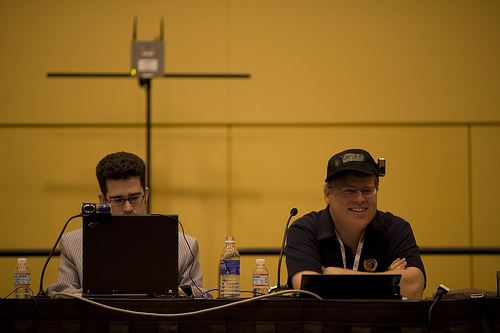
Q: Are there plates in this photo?
A: No, there are no plates.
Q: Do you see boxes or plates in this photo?
A: No, there are no plates or boxes.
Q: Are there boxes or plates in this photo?
A: No, there are no plates or boxes.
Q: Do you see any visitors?
A: No, there are no visitors.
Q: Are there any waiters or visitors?
A: No, there are no visitors or waiters.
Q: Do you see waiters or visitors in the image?
A: No, there are no visitors or waiters.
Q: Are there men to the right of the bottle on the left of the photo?
A: Yes, there is a man to the right of the bottle.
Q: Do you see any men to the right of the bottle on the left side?
A: Yes, there is a man to the right of the bottle.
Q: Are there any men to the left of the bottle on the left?
A: No, the man is to the right of the bottle.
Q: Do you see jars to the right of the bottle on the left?
A: No, there is a man to the right of the bottle.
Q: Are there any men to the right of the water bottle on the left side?
A: Yes, there is a man to the right of the water bottle.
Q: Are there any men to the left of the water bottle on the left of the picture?
A: No, the man is to the right of the water bottle.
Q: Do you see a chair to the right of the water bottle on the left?
A: No, there is a man to the right of the water bottle.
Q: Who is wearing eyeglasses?
A: The man is wearing eyeglasses.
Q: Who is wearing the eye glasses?
A: The man is wearing eyeglasses.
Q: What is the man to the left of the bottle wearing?
A: The man is wearing eyeglasses.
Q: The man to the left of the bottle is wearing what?
A: The man is wearing eyeglasses.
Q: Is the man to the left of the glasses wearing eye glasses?
A: Yes, the man is wearing eye glasses.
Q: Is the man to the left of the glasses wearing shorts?
A: No, the man is wearing eye glasses.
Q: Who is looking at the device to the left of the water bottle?
A: The man is looking at the computer.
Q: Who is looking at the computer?
A: The man is looking at the computer.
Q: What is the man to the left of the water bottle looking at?
A: The man is looking at the computer.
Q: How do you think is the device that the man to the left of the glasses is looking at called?
A: The device is a computer.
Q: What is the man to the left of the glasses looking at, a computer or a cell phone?
A: The man is looking at a computer.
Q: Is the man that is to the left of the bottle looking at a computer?
A: Yes, the man is looking at a computer.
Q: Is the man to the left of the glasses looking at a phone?
A: No, the man is looking at a computer.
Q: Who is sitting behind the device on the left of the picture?
A: The man is sitting behind the computer.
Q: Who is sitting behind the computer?
A: The man is sitting behind the computer.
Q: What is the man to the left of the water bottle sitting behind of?
A: The man is sitting behind the computer.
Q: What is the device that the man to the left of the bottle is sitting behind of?
A: The device is a computer.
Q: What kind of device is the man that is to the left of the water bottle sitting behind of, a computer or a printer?
A: The man is sitting behind a computer.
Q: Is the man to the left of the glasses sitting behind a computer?
A: Yes, the man is sitting behind a computer.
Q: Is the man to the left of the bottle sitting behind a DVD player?
A: No, the man is sitting behind a computer.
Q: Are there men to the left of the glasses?
A: Yes, there is a man to the left of the glasses.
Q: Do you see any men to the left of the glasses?
A: Yes, there is a man to the left of the glasses.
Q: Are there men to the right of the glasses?
A: No, the man is to the left of the glasses.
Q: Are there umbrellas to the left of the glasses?
A: No, there is a man to the left of the glasses.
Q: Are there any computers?
A: Yes, there is a computer.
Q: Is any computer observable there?
A: Yes, there is a computer.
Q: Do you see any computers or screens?
A: Yes, there is a computer.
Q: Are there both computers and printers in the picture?
A: No, there is a computer but no printers.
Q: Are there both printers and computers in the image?
A: No, there is a computer but no printers.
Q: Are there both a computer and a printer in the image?
A: No, there is a computer but no printers.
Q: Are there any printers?
A: No, there are no printers.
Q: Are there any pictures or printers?
A: No, there are no printers or pictures.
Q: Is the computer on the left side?
A: Yes, the computer is on the left of the image.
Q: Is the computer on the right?
A: No, the computer is on the left of the image.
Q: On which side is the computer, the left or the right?
A: The computer is on the left of the image.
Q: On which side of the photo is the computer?
A: The computer is on the left of the image.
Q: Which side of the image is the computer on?
A: The computer is on the left of the image.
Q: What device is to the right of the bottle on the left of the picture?
A: The device is a computer.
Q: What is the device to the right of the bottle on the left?
A: The device is a computer.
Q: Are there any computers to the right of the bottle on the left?
A: Yes, there is a computer to the right of the bottle.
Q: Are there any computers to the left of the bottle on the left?
A: No, the computer is to the right of the bottle.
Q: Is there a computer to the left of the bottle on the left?
A: No, the computer is to the right of the bottle.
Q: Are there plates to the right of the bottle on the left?
A: No, there is a computer to the right of the bottle.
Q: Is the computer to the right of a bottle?
A: Yes, the computer is to the right of a bottle.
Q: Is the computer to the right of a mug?
A: No, the computer is to the right of a bottle.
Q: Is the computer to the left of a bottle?
A: No, the computer is to the right of a bottle.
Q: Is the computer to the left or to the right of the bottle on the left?
A: The computer is to the right of the bottle.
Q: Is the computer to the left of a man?
A: Yes, the computer is to the left of a man.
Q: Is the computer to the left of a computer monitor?
A: No, the computer is to the left of a man.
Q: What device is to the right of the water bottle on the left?
A: The device is a computer.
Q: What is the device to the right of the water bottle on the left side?
A: The device is a computer.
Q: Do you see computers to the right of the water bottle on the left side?
A: Yes, there is a computer to the right of the water bottle.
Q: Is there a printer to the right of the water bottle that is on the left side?
A: No, there is a computer to the right of the water bottle.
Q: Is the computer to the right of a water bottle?
A: Yes, the computer is to the right of a water bottle.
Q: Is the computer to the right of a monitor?
A: No, the computer is to the right of a water bottle.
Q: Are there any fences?
A: No, there are no fences.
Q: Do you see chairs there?
A: No, there are no chairs.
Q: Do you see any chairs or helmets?
A: No, there are no chairs or helmets.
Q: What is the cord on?
A: The cord is on the table.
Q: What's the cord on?
A: The cord is on the table.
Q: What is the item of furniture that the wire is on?
A: The piece of furniture is a table.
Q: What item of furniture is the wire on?
A: The wire is on the table.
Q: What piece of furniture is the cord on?
A: The wire is on the table.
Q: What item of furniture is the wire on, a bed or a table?
A: The wire is on a table.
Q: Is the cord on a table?
A: Yes, the cord is on a table.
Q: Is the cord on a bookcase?
A: No, the cord is on a table.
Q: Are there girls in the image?
A: No, there are no girls.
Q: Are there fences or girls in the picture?
A: No, there are no girls or fences.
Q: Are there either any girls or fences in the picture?
A: No, there are no girls or fences.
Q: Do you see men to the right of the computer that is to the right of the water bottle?
A: Yes, there is a man to the right of the computer.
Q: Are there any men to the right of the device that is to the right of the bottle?
A: Yes, there is a man to the right of the computer.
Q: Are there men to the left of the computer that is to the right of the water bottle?
A: No, the man is to the right of the computer.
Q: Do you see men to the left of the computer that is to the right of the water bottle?
A: No, the man is to the right of the computer.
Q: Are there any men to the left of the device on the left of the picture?
A: No, the man is to the right of the computer.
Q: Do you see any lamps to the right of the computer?
A: No, there is a man to the right of the computer.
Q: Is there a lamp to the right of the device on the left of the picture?
A: No, there is a man to the right of the computer.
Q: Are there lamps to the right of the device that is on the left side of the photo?
A: No, there is a man to the right of the computer.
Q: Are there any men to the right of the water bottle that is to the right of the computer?
A: Yes, there is a man to the right of the water bottle.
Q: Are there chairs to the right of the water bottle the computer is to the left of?
A: No, there is a man to the right of the water bottle.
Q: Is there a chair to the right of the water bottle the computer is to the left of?
A: No, there is a man to the right of the water bottle.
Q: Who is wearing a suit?
A: The man is wearing a suit.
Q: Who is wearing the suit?
A: The man is wearing a suit.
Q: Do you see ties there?
A: No, there are no ties.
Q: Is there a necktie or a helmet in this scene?
A: No, there are no ties or helmets.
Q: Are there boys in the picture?
A: No, there are no boys.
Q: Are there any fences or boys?
A: No, there are no boys or fences.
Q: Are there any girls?
A: No, there are no girls.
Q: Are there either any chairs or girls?
A: No, there are no girls or chairs.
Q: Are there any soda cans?
A: No, there are no soda cans.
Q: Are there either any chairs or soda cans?
A: No, there are no soda cans or chairs.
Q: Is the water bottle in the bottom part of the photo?
A: Yes, the water bottle is in the bottom of the image.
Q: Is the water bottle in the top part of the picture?
A: No, the water bottle is in the bottom of the image.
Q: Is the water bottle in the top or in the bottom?
A: The water bottle is in the bottom of the image.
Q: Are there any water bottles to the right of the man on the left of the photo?
A: Yes, there is a water bottle to the right of the man.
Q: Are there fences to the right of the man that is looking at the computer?
A: No, there is a water bottle to the right of the man.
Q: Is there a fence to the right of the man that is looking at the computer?
A: No, there is a water bottle to the right of the man.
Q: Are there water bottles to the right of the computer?
A: Yes, there is a water bottle to the right of the computer.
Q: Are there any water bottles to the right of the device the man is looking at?
A: Yes, there is a water bottle to the right of the computer.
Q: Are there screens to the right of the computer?
A: No, there is a water bottle to the right of the computer.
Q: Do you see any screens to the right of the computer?
A: No, there is a water bottle to the right of the computer.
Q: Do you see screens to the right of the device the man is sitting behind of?
A: No, there is a water bottle to the right of the computer.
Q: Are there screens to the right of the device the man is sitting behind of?
A: No, there is a water bottle to the right of the computer.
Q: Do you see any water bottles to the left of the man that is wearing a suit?
A: Yes, there is a water bottle to the left of the man.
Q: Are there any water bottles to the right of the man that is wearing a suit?
A: No, the water bottle is to the left of the man.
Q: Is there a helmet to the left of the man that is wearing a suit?
A: No, there is a water bottle to the left of the man.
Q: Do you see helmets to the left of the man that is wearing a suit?
A: No, there is a water bottle to the left of the man.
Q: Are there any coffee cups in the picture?
A: No, there are no coffee cups.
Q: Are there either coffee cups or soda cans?
A: No, there are no coffee cups or soda cans.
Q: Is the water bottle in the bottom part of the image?
A: Yes, the water bottle is in the bottom of the image.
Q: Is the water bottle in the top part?
A: No, the water bottle is in the bottom of the image.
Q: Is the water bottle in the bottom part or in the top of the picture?
A: The water bottle is in the bottom of the image.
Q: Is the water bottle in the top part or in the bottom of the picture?
A: The water bottle is in the bottom of the image.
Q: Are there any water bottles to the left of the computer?
A: Yes, there is a water bottle to the left of the computer.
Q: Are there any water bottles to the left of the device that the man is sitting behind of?
A: Yes, there is a water bottle to the left of the computer.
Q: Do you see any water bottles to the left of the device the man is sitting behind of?
A: Yes, there is a water bottle to the left of the computer.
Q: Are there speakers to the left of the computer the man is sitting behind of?
A: No, there is a water bottle to the left of the computer.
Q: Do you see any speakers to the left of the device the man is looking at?
A: No, there is a water bottle to the left of the computer.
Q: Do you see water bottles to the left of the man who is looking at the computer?
A: Yes, there is a water bottle to the left of the man.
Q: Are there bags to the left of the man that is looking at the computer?
A: No, there is a water bottle to the left of the man.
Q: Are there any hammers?
A: No, there are no hammers.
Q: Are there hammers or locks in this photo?
A: No, there are no hammers or locks.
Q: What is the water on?
A: The water is on the table.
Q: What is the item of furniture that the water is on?
A: The piece of furniture is a table.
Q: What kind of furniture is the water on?
A: The water is on the table.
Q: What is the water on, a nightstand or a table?
A: The water is on a table.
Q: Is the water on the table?
A: Yes, the water is on the table.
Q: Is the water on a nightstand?
A: No, the water is on the table.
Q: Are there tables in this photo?
A: Yes, there is a table.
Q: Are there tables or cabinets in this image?
A: Yes, there is a table.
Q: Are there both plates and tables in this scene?
A: No, there is a table but no plates.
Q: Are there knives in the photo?
A: No, there are no knives.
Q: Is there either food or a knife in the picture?
A: No, there are no knives or food.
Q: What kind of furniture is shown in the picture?
A: The furniture is a table.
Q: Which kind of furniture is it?
A: The piece of furniture is a table.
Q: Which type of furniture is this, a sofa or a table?
A: This is a table.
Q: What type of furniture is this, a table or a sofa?
A: This is a table.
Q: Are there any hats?
A: Yes, there is a hat.